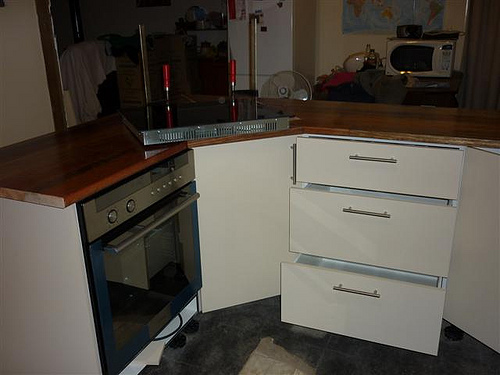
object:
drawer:
[288, 129, 465, 200]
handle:
[340, 203, 393, 219]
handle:
[332, 284, 385, 303]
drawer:
[268, 257, 449, 365]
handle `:
[348, 153, 399, 166]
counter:
[0, 88, 500, 210]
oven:
[82, 150, 203, 373]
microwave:
[371, 29, 470, 86]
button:
[105, 207, 120, 225]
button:
[126, 197, 138, 212]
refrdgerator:
[225, 0, 314, 99]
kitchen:
[0, 4, 499, 375]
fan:
[259, 66, 316, 103]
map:
[344, 2, 448, 34]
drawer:
[286, 185, 459, 275]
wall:
[312, 0, 342, 62]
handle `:
[98, 190, 205, 259]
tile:
[169, 320, 265, 375]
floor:
[144, 306, 500, 374]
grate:
[140, 114, 292, 150]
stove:
[118, 95, 295, 151]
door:
[91, 226, 186, 293]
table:
[332, 77, 473, 103]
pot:
[395, 23, 427, 41]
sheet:
[61, 49, 107, 125]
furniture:
[98, 82, 122, 110]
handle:
[225, 60, 241, 96]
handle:
[159, 63, 175, 99]